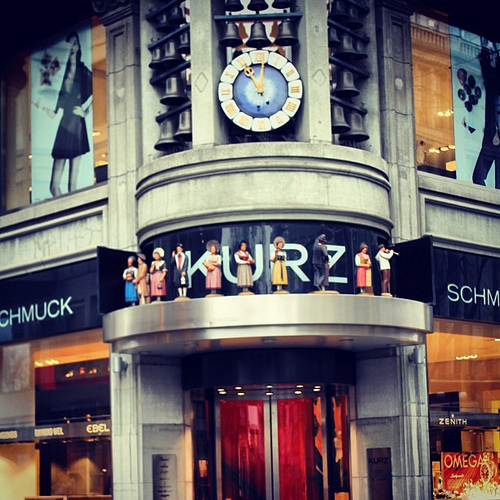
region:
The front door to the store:
[202, 376, 337, 496]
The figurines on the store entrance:
[115, 231, 401, 304]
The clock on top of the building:
[212, 47, 304, 133]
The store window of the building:
[0, 285, 101, 490]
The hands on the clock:
[240, 55, 270, 91]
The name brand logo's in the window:
[0, 417, 106, 444]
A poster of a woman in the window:
[20, 40, 110, 201]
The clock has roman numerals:
[207, 45, 305, 128]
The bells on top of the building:
[125, 5, 207, 150]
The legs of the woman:
[37, 143, 84, 198]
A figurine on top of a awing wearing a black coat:
[175, 241, 192, 300]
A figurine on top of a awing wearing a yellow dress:
[264, 240, 299, 283]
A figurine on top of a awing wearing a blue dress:
[124, 249, 131, 299]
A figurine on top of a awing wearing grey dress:
[232, 240, 247, 295]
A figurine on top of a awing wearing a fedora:
[370, 237, 395, 298]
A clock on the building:
[210, 50, 316, 134]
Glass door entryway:
[217, 383, 334, 498]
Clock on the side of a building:
[206, 43, 316, 128]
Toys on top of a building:
[107, 236, 412, 296]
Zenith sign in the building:
[426, 406, 473, 431]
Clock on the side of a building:
[221, 38, 306, 138]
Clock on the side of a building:
[203, 35, 319, 133]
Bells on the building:
[329, 20, 371, 140]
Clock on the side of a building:
[211, 45, 304, 125]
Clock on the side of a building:
[211, 46, 308, 126]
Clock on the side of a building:
[210, 37, 309, 139]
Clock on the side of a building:
[208, 45, 305, 143]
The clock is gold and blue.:
[218, 48, 305, 130]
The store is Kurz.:
[168, 246, 360, 288]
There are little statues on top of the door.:
[115, 229, 411, 299]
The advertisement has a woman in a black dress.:
[21, 32, 101, 199]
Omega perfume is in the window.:
[439, 451, 497, 489]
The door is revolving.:
[178, 346, 363, 498]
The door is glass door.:
[182, 350, 361, 499]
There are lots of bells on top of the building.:
[149, 0, 381, 152]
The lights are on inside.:
[428, 336, 499, 488]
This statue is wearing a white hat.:
[149, 248, 167, 300]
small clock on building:
[210, 51, 302, 135]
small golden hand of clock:
[238, 62, 256, 97]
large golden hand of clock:
[258, 49, 272, 86]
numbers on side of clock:
[287, 59, 301, 90]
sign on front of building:
[112, 232, 404, 296]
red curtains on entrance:
[228, 403, 318, 498]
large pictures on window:
[27, 29, 94, 199]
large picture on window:
[454, 38, 496, 175]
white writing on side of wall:
[0, 292, 91, 333]